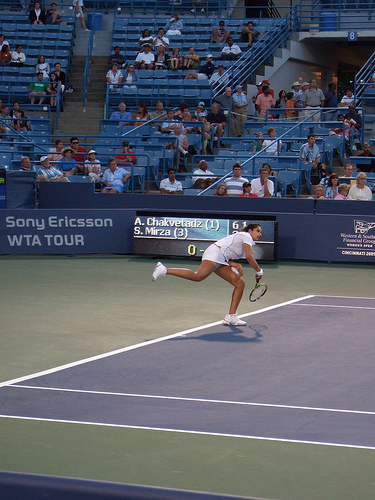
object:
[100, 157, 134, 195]
spectator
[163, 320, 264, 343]
shadow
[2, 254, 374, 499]
ground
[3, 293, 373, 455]
surface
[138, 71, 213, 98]
blue bleachers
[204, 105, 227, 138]
spectator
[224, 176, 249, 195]
shirt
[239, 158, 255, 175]
seat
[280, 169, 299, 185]
seat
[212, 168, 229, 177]
seat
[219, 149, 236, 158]
seat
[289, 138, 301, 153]
seat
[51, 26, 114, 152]
stairs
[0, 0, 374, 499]
stadium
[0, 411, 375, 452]
lines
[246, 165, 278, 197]
spectator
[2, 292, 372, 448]
court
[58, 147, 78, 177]
person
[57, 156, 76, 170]
shirt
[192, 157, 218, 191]
spectator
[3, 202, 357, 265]
wall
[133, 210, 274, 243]
scoreboard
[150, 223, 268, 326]
game controller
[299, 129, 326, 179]
man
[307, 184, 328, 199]
spectator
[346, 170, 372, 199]
spectator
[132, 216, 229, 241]
sign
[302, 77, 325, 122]
man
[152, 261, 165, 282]
shoes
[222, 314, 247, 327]
shoes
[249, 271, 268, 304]
tennis racket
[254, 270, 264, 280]
hand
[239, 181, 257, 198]
spectator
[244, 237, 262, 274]
arm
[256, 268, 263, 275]
wristband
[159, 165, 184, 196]
man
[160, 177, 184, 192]
shirt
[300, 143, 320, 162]
shirt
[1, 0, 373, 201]
stands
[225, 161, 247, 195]
man